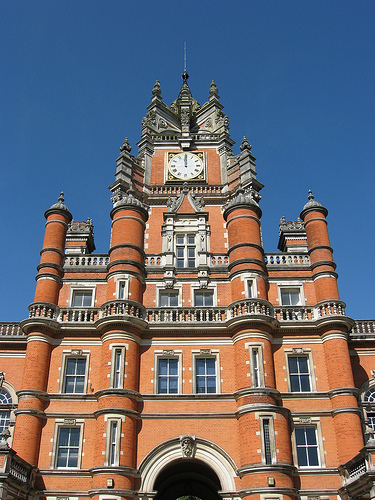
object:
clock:
[164, 151, 208, 185]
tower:
[45, 37, 312, 498]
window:
[158, 359, 180, 396]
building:
[0, 57, 375, 500]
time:
[170, 153, 202, 178]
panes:
[169, 359, 178, 375]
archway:
[139, 437, 243, 499]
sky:
[27, 9, 356, 81]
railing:
[6, 454, 32, 484]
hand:
[184, 154, 187, 166]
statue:
[179, 434, 196, 458]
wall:
[157, 393, 271, 436]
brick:
[208, 427, 219, 439]